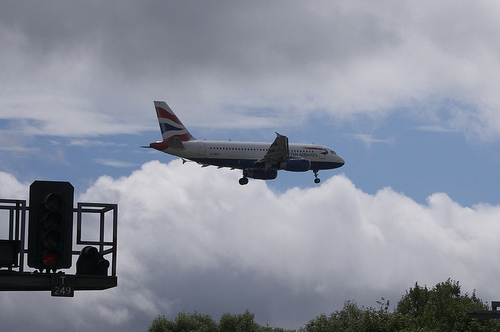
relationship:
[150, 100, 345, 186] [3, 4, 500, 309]
plane in air